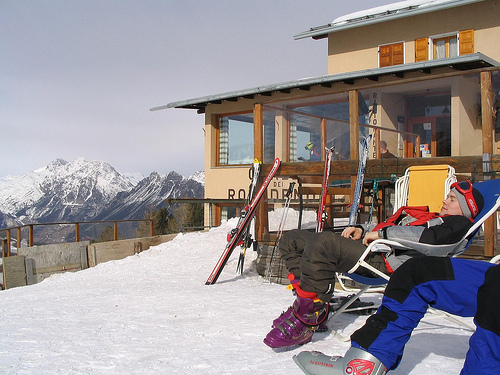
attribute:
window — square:
[426, 28, 462, 65]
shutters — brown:
[456, 28, 477, 60]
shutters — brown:
[413, 33, 429, 70]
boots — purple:
[253, 271, 340, 359]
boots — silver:
[285, 330, 399, 375]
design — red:
[335, 353, 379, 374]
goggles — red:
[447, 177, 484, 221]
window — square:
[374, 35, 407, 78]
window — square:
[208, 100, 282, 178]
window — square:
[277, 89, 378, 180]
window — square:
[387, 79, 470, 122]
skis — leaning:
[228, 153, 270, 286]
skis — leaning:
[195, 157, 285, 291]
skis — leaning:
[303, 140, 345, 250]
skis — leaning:
[341, 127, 379, 248]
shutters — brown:
[380, 43, 403, 70]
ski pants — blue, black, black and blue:
[346, 245, 499, 372]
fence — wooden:
[0, 215, 164, 262]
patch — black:
[383, 252, 458, 304]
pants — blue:
[427, 250, 494, 324]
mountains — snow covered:
[31, 152, 158, 206]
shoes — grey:
[286, 333, 390, 373]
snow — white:
[115, 252, 215, 337]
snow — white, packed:
[3, 207, 499, 374]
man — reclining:
[278, 175, 485, 335]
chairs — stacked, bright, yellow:
[388, 162, 459, 214]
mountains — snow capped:
[0, 156, 207, 258]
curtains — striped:
[211, 132, 244, 156]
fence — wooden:
[0, 216, 158, 258]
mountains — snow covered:
[2, 156, 204, 227]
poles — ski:
[265, 181, 302, 293]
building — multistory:
[149, 0, 494, 220]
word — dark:
[225, 186, 315, 203]